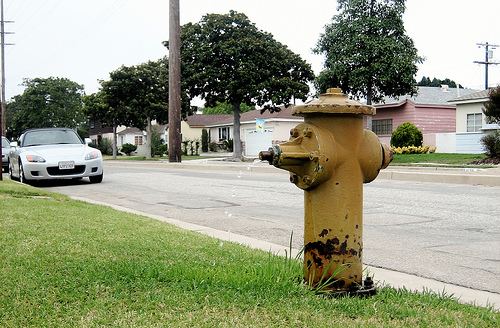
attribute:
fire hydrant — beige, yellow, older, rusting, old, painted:
[259, 81, 396, 300]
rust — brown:
[306, 230, 358, 266]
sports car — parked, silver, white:
[3, 122, 108, 183]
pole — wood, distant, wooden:
[161, 0, 187, 160]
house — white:
[443, 84, 499, 153]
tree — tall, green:
[180, 8, 301, 162]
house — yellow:
[191, 108, 304, 152]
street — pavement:
[81, 156, 499, 290]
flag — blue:
[252, 116, 265, 133]